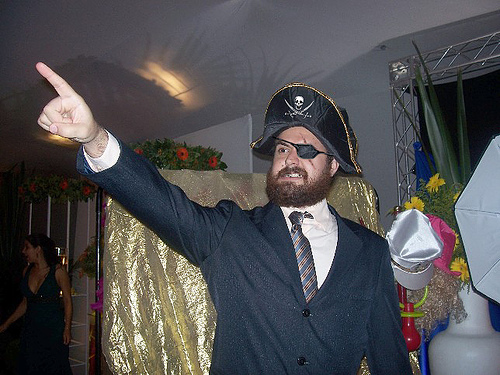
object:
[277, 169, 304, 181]
mouth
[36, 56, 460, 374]
person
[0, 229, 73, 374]
woman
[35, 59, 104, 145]
hand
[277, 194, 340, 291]
white shirt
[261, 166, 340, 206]
beard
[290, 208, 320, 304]
tie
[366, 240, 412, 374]
arm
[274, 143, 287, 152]
eye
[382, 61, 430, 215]
stand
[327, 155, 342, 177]
ear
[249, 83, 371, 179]
hat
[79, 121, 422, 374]
blazer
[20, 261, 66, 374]
dress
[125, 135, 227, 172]
decoration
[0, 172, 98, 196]
decoration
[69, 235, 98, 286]
decoration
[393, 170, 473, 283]
decoration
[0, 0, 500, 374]
photo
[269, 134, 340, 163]
eye patch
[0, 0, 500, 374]
house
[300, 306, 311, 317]
button